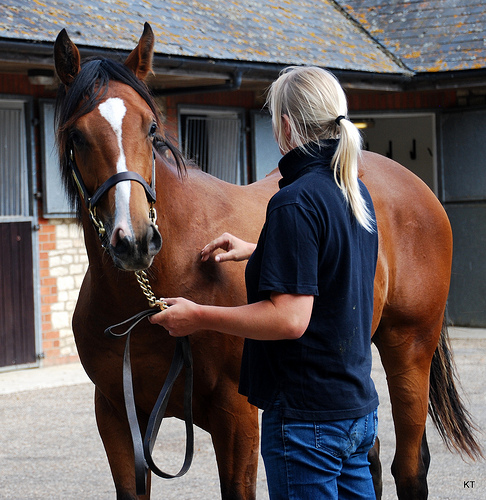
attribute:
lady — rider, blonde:
[150, 61, 384, 499]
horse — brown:
[50, 26, 485, 500]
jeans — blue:
[257, 411, 382, 500]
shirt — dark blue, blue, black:
[238, 137, 384, 418]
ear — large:
[123, 18, 157, 85]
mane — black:
[46, 49, 202, 214]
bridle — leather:
[64, 101, 163, 252]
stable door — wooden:
[2, 99, 40, 372]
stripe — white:
[92, 93, 143, 241]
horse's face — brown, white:
[49, 18, 177, 281]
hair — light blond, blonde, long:
[267, 61, 380, 235]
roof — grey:
[2, 0, 486, 75]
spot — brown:
[401, 48, 422, 60]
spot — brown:
[246, 45, 271, 58]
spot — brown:
[90, 13, 112, 21]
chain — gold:
[129, 268, 171, 310]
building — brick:
[2, 0, 486, 372]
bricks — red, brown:
[2, 75, 256, 365]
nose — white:
[56, 160, 178, 270]